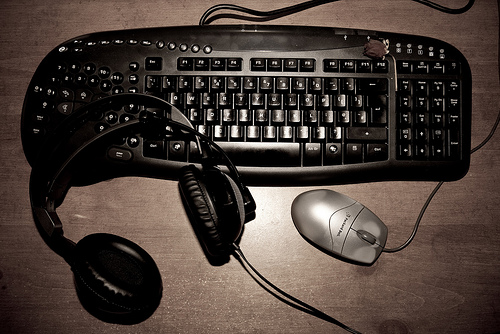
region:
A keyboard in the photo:
[178, 54, 348, 161]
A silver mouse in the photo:
[286, 201, 391, 261]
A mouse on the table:
[293, 189, 402, 264]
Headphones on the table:
[45, 162, 247, 302]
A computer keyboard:
[80, 37, 417, 161]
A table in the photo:
[410, 247, 480, 309]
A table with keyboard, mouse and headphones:
[15, 17, 455, 294]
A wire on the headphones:
[251, 244, 328, 323]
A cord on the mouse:
[393, 188, 455, 235]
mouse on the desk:
[285, 195, 389, 266]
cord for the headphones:
[235, 275, 359, 326]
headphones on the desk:
[37, 110, 218, 313]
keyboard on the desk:
[25, 21, 462, 172]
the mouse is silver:
[322, 217, 360, 262]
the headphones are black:
[110, 265, 150, 301]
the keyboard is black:
[267, 40, 339, 85]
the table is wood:
[388, 286, 453, 322]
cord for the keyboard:
[207, 0, 320, 22]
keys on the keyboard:
[212, 77, 324, 115]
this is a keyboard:
[0, 15, 465, 257]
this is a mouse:
[286, 187, 403, 291]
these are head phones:
[22, 93, 257, 318]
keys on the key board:
[224, 98, 259, 134]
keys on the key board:
[191, 82, 248, 128]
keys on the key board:
[285, 73, 345, 125]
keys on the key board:
[181, 90, 236, 140]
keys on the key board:
[413, 94, 454, 124]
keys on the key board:
[152, 73, 210, 119]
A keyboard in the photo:
[232, 62, 298, 134]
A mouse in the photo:
[291, 193, 385, 257]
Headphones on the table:
[57, 125, 247, 291]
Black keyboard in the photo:
[226, 56, 382, 129]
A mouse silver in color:
[285, 186, 383, 259]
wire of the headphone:
[270, 282, 334, 320]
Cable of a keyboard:
[194, 4, 266, 26]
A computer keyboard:
[33, 30, 452, 162]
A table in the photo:
[422, 266, 465, 313]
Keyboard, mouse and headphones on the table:
[34, 51, 450, 296]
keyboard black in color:
[20, 25, 475, 181]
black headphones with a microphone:
[26, 92, 253, 323]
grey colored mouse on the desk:
[291, 188, 388, 266]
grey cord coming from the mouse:
[383, 112, 499, 274]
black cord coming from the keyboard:
[192, 0, 499, 26]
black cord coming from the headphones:
[232, 245, 363, 332]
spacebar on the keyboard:
[191, 138, 301, 163]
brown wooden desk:
[1, 2, 496, 332]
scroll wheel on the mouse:
[362, 231, 376, 242]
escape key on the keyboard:
[147, 57, 162, 67]